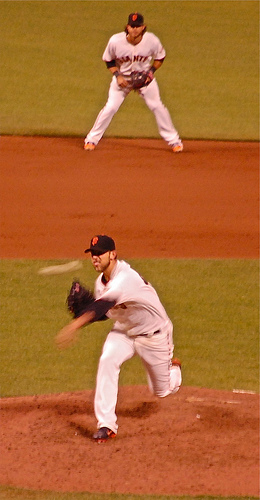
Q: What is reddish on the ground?
A: Dirt.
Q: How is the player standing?
A: Feet apart.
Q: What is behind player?
A: Grass.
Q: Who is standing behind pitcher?
A: Player.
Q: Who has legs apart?
A: Player.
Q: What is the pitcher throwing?
A: Ball.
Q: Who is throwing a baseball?
A: A pitcher.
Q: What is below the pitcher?
A: The baseball mound.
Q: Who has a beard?
A: The pitcher.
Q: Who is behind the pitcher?
A: The shortstop.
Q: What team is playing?
A: Giants.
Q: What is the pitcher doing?
A: Pitching.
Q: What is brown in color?
A: The dirt.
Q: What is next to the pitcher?
A: Grass.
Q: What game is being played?
A: Baseball.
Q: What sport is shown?
A: Baseball.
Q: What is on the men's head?
A: Hat.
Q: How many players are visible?
A: Two.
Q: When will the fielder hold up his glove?
A: When he sees the ball coming his way.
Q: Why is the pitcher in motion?
A: He is throwing the ball.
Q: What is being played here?
A: Baseball.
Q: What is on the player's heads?
A: Caps.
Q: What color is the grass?
A: Green.